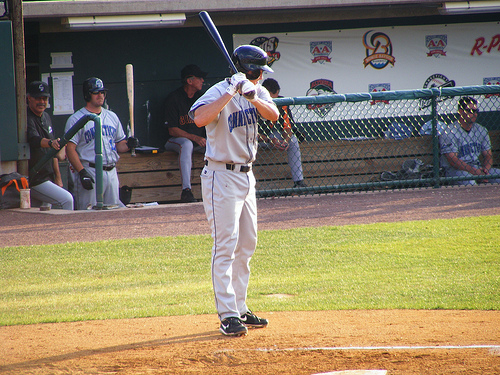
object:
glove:
[236, 80, 261, 103]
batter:
[226, 71, 245, 98]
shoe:
[219, 317, 250, 338]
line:
[322, 345, 499, 350]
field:
[11, 172, 497, 372]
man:
[29, 81, 74, 210]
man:
[154, 63, 211, 203]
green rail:
[28, 114, 106, 215]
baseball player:
[186, 43, 280, 338]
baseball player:
[437, 95, 500, 185]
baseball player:
[65, 76, 141, 210]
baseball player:
[258, 78, 307, 193]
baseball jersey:
[188, 78, 276, 165]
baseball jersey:
[437, 121, 492, 170]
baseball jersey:
[63, 107, 125, 166]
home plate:
[309, 362, 383, 375]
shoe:
[238, 311, 268, 329]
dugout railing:
[252, 87, 497, 198]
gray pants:
[198, 165, 257, 320]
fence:
[316, 93, 388, 183]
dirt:
[357, 320, 436, 349]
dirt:
[410, 353, 496, 375]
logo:
[362, 29, 397, 71]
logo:
[309, 40, 334, 66]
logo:
[306, 78, 339, 119]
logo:
[424, 33, 449, 58]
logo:
[471, 34, 500, 56]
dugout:
[108, 147, 490, 204]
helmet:
[231, 45, 275, 74]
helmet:
[82, 77, 109, 101]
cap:
[27, 81, 50, 99]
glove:
[225, 71, 248, 98]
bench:
[123, 131, 434, 201]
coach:
[27, 79, 75, 211]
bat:
[126, 64, 136, 137]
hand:
[126, 136, 140, 147]